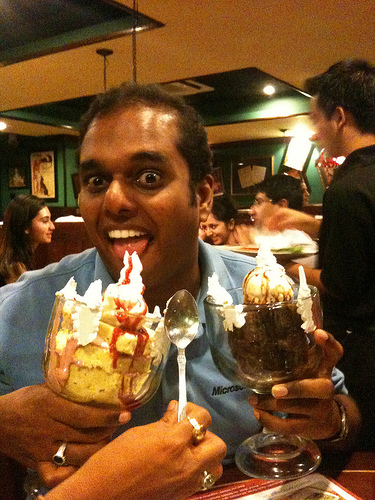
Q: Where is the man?
A: Restaurant.